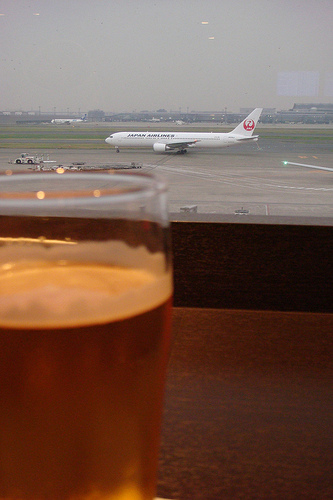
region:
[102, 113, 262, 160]
the plane is on the runway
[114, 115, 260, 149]
the airline is japan airline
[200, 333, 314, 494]
table is wooden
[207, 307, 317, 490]
the table is brown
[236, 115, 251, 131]
a logo is on the tail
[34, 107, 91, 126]
plane is in the background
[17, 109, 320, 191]
the scenery is at an airport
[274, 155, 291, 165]
light on wing is green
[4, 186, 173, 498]
the glass has beer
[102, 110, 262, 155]
the plane is white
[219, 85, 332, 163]
wing of a japan airplane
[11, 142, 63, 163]
luggage carrier for the airline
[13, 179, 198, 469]
glass of beer on the table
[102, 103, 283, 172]
japan airlines airplane on the runway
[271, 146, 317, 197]
green light on an airplane wing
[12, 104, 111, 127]
blue airplane off in the distance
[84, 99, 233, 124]
airport off in the distance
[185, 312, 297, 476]
brown table in the distance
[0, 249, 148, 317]
suds on a beer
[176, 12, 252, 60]
light reflection on the window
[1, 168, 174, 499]
Very close glass of foamy beer.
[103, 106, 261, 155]
White airplane closest to the window.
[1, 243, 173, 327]
Foamy head of the glass of beer.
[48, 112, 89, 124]
The furthest white plane.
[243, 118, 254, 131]
Red logo on the tail end of the closest plane.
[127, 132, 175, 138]
JAPAN AIRLINES written on the side of a white plane.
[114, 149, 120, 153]
Black wheels at the front of the closest plane.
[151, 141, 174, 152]
White and silver engine on this side of the closest plane.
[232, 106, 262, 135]
White tail end of the closest plane with red logo on it.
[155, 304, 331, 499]
Wood top of the table to the right of a beer.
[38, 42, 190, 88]
The sky is gray and clear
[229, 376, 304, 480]
The table is made of wood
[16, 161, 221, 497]
The glass is on the table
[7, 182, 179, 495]
The glass is full of beer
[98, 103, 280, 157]
The airplane is on the ground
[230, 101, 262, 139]
The back wing of the airplane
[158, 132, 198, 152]
The wing of the airplane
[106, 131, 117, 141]
The cockpit of the airplane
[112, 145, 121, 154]
The wheel of the airplane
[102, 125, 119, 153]
The nose of the airplane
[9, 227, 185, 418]
This is a picture of a glass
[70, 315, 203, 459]
The glass is full of beer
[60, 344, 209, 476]
The beer is brown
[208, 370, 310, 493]
This is a wooden table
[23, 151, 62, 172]
This is a small car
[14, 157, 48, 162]
These are wheels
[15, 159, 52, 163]
The wheels are made of rubber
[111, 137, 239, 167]
This is an airplane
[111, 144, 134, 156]
These are wheels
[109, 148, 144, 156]
The wheels are black